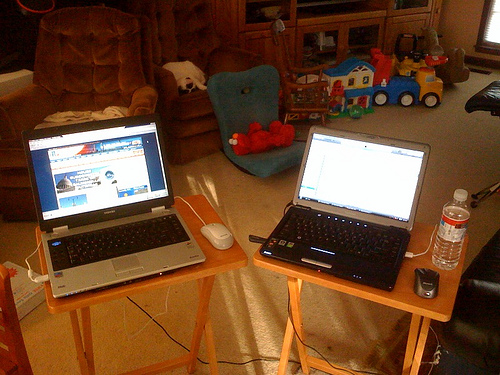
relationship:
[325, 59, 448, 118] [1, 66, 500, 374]
toy on floor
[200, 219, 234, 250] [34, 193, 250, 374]
mouse on computer desk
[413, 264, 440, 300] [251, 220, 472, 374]
mouse on computer desk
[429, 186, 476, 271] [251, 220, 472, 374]
water bottle on computer desk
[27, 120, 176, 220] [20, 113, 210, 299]
screen of computer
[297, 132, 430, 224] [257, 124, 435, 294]
screen on computer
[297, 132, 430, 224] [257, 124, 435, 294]
screen of computer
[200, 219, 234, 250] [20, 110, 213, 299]
mouse for laptop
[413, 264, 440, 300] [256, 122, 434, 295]
mouse for laptop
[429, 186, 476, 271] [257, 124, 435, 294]
water bottle by computer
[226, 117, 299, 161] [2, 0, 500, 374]
stuffed animal in room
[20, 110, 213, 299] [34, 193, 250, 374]
laptop on computer desk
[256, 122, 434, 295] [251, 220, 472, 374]
laptop on computer desk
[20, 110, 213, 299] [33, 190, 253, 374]
laptop on stand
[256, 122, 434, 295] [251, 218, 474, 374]
laptop on stand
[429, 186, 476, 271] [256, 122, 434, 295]
water bottle next to laptop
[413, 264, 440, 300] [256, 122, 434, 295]
mouse on right next to laptop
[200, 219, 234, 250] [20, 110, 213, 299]
mouse on left next to laptop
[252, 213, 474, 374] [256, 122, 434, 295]
tv table on right with laptop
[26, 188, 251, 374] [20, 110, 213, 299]
tv table on left with laptop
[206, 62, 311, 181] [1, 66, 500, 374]
game chair on floor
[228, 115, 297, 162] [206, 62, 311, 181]
tickle me elmo on game chair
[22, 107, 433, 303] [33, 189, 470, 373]
laptops on tables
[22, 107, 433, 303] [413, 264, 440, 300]
laptops with mouse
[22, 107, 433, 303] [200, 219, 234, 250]
laptops with mouse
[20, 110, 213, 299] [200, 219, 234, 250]
laptop with mouse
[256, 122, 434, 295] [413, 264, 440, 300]
laptop with mouse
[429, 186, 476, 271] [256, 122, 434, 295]
water bottle near laptop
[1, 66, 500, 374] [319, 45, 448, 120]
floor full of toy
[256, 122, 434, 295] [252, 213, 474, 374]
laptop of tv table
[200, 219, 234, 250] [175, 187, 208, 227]
mouse with cord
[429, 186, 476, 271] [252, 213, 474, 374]
water bottle on tv table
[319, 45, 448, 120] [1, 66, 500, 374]
toy on floor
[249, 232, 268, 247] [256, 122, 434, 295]
flash drive plugged into laptop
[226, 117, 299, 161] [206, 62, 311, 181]
stuffed animal on game chair